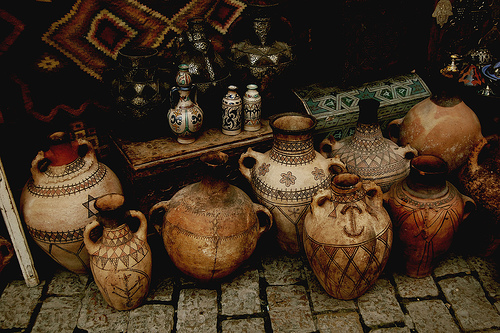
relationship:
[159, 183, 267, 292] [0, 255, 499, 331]
pottery on floor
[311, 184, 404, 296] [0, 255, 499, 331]
pot on floor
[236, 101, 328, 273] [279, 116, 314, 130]
jug has opening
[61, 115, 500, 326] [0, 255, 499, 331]
vases on floor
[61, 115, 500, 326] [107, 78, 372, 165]
vases on top of table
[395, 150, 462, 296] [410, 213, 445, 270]
vase has design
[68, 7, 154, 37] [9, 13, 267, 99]
design on blanket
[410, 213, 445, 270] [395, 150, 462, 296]
design on vase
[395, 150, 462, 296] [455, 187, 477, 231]
vase has handle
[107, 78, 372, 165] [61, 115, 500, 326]
table behind vases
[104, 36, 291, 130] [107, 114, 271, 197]
vases on table